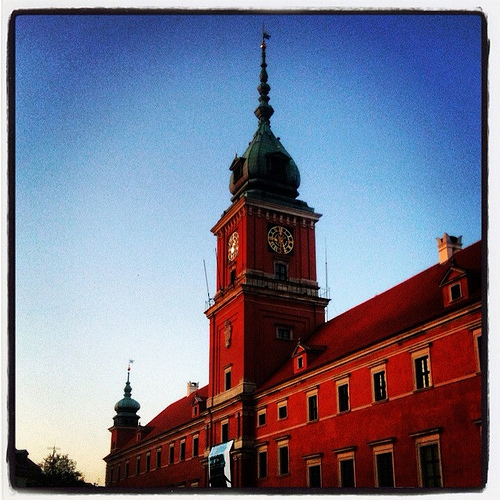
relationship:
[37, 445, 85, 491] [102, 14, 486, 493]
green trees in back of building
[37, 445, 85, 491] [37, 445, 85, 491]
green trees in back of green trees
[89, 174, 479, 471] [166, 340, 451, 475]
building has windows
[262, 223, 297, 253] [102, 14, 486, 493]
clock at top of building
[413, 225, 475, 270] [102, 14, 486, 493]
chimney at top of building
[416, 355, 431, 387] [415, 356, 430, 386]
window has courtain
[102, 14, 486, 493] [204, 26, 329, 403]
building has tower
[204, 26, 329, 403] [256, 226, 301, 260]
tower has clock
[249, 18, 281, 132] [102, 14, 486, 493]
turret on building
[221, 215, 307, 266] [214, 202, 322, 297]
clocks are on wall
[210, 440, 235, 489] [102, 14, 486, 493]
banner fitted on building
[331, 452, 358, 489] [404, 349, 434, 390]
window in window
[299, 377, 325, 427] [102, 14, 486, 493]
window in building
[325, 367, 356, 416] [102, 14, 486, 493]
window in building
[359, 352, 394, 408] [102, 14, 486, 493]
window in building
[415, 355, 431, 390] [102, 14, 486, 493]
window in building